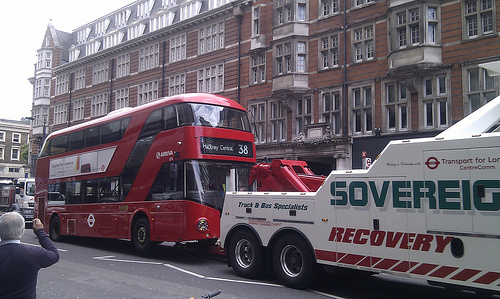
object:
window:
[172, 101, 253, 134]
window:
[137, 101, 194, 140]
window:
[116, 52, 131, 80]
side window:
[58, 175, 83, 198]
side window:
[89, 179, 119, 200]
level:
[45, 199, 186, 208]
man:
[1, 207, 63, 297]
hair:
[0, 210, 27, 240]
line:
[90, 254, 347, 299]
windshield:
[183, 160, 258, 213]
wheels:
[271, 229, 320, 285]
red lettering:
[326, 224, 454, 254]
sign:
[38, 139, 141, 195]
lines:
[158, 261, 207, 279]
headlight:
[194, 217, 210, 233]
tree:
[18, 143, 30, 165]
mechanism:
[271, 159, 309, 192]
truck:
[248, 158, 328, 192]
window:
[121, 116, 132, 136]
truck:
[0, 177, 36, 224]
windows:
[66, 179, 84, 203]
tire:
[242, 214, 323, 296]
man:
[4, 209, 59, 274]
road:
[18, 216, 374, 296]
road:
[20, 229, 390, 293]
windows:
[99, 174, 122, 202]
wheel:
[132, 218, 157, 258]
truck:
[215, 95, 497, 295]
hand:
[32, 218, 44, 232]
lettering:
[328, 177, 500, 213]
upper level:
[35, 91, 258, 184]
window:
[48, 133, 69, 156]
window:
[68, 130, 85, 152]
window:
[85, 125, 100, 148]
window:
[100, 118, 123, 144]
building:
[27, 0, 498, 178]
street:
[17, 225, 443, 297]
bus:
[33, 91, 258, 256]